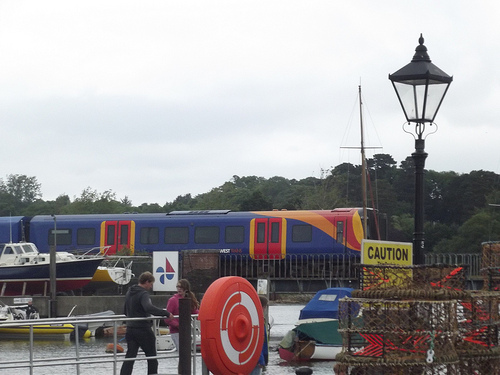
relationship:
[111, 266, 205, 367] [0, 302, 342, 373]
people walking along dock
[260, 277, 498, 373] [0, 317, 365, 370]
boats are in water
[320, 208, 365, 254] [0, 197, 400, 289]
trim on train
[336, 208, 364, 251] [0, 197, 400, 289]
trim on train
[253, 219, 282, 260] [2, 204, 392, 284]
door are on train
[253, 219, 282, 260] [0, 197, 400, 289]
door are on train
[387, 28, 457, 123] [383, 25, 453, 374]
lamp on post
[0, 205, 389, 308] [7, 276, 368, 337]
train on tracks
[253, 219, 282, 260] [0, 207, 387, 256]
door on train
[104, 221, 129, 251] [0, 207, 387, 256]
door on train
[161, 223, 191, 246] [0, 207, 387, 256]
window on train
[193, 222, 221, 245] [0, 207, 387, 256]
window on train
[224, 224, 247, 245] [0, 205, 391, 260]
window on train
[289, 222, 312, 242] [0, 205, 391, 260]
window on train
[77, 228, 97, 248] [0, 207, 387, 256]
window on train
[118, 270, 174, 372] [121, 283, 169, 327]
man wearing hoodie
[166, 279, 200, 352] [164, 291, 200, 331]
woman wearing sweater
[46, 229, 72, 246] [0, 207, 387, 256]
window on train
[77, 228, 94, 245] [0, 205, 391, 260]
window on train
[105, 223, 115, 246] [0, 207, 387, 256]
window on train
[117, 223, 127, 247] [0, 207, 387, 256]
window on train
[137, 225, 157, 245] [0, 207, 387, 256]
window on train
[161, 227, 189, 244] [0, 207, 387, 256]
window on train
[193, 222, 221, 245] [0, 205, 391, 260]
window on train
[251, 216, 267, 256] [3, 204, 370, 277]
window on train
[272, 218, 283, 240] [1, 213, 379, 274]
window on train